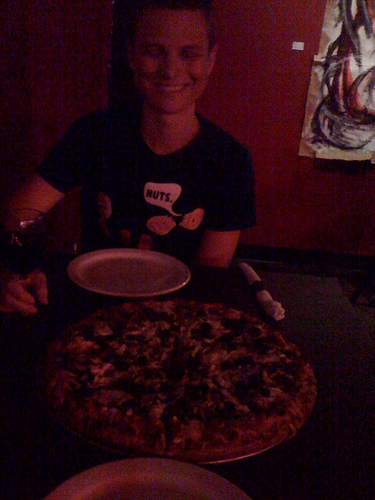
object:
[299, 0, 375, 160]
paper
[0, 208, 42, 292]
wineglass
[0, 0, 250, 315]
guy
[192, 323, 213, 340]
sausage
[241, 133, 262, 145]
ground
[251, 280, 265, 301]
silverware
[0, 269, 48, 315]
hand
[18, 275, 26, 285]
wine stem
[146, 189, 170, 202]
writing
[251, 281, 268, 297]
ring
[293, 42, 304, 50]
square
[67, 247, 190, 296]
plate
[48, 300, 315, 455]
cheese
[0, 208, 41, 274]
glass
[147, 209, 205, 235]
peanut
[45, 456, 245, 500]
partial plate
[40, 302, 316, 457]
pizza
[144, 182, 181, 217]
design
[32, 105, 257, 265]
t shirt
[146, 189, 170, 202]
word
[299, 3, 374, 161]
painting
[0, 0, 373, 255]
wall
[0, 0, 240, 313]
man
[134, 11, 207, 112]
face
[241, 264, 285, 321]
napkin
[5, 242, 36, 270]
wine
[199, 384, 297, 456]
crust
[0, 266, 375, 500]
table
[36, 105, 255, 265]
shirt